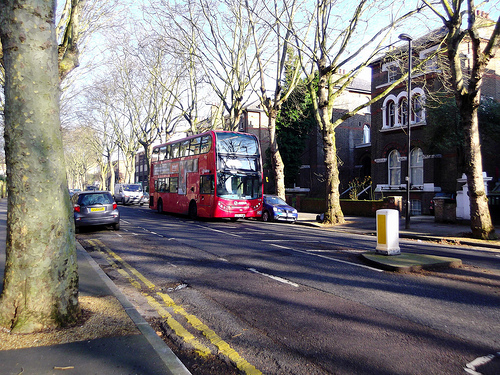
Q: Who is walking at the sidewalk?
A: No one.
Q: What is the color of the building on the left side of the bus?
A: Brown.